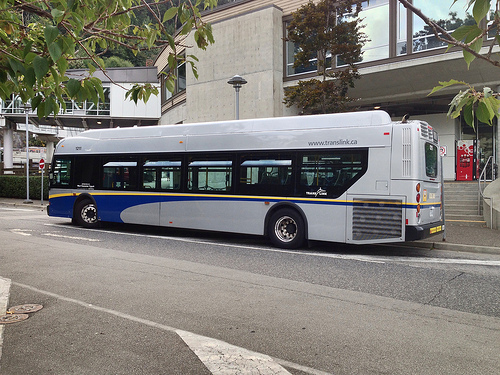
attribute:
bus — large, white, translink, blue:
[38, 106, 454, 260]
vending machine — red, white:
[450, 133, 483, 183]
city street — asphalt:
[2, 197, 499, 375]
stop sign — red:
[34, 158, 47, 171]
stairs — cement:
[430, 175, 492, 230]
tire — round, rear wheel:
[261, 203, 311, 252]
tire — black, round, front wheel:
[72, 194, 106, 229]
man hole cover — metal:
[2, 296, 45, 326]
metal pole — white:
[228, 86, 246, 120]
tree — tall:
[282, 0, 363, 109]